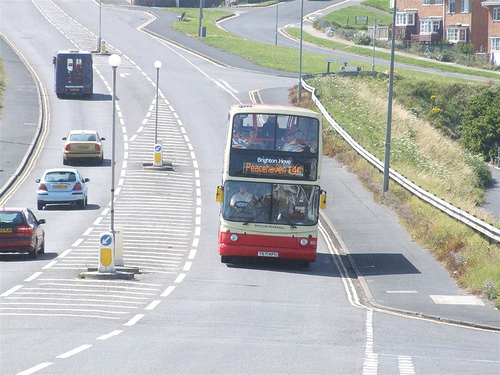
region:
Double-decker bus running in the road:
[208, 86, 338, 278]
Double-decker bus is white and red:
[210, 90, 335, 275]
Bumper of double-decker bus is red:
[211, 241, 321, 274]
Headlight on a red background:
[224, 230, 314, 249]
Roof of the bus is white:
[222, 95, 326, 127]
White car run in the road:
[26, 159, 96, 215]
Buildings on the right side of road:
[390, 5, 499, 70]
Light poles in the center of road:
[96, 42, 172, 287]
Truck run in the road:
[48, 40, 101, 104]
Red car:
[0, 201, 59, 264]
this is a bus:
[210, 101, 325, 258]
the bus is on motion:
[220, 107, 324, 257]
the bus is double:
[221, 107, 321, 249]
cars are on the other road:
[12, 43, 102, 267]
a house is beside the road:
[406, 3, 496, 55]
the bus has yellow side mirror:
[317, 191, 329, 208]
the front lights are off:
[229, 230, 313, 248]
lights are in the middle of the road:
[94, 56, 174, 274]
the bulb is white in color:
[109, 47, 120, 64]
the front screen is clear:
[226, 183, 316, 224]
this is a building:
[400, 0, 495, 60]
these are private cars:
[5, 45, 105, 240]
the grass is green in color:
[435, 85, 480, 125]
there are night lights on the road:
[105, 40, 170, 260]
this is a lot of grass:
[419, 80, 466, 170]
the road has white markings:
[115, 187, 202, 228]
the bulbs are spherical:
[104, 49, 169, 71]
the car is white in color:
[45, 175, 84, 200]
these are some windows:
[401, 10, 472, 45]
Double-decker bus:
[203, 85, 332, 279]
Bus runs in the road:
[205, 91, 330, 277]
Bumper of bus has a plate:
[211, 244, 320, 266]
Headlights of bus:
[222, 230, 312, 252]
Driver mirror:
[313, 189, 330, 212]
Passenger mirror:
[211, 183, 226, 205]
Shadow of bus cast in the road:
[319, 236, 421, 291]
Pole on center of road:
[96, 41, 138, 274]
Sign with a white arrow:
[93, 229, 123, 276]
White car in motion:
[31, 160, 93, 213]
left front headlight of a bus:
[293, 233, 311, 251]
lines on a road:
[155, 185, 192, 277]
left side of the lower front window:
[272, 190, 310, 223]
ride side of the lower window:
[225, 177, 260, 226]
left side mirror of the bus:
[315, 190, 327, 215]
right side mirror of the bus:
[211, 183, 232, 205]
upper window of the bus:
[244, 112, 305, 167]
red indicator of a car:
[94, 140, 99, 153]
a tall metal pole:
[386, 5, 394, 197]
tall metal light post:
[96, 42, 125, 257]